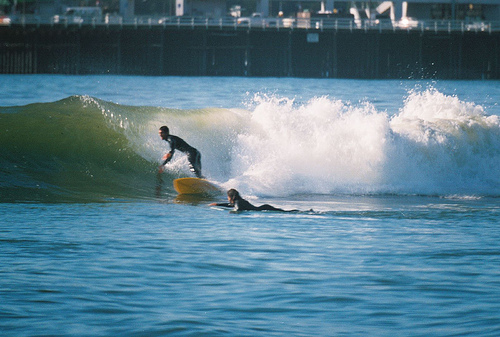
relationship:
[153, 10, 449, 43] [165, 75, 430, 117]
bridge over water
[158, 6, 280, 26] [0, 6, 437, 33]
traffic on bridge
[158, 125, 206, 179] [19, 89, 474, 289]
guy surfing in water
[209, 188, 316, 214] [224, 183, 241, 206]
people has hair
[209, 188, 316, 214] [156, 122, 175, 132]
people has hair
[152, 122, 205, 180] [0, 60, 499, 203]
guy surfing on a wave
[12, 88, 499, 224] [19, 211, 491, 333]
wave forming in ocean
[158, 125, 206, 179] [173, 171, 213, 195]
guy standing on surfboard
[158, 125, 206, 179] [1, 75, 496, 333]
guy surfing in water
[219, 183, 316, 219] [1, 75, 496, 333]
people surfing in water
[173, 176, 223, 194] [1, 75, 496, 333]
surfboard in water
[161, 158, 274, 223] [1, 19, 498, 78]
pole in board walk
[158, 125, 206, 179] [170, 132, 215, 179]
guy wearing suit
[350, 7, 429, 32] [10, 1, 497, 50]
airplane in sky